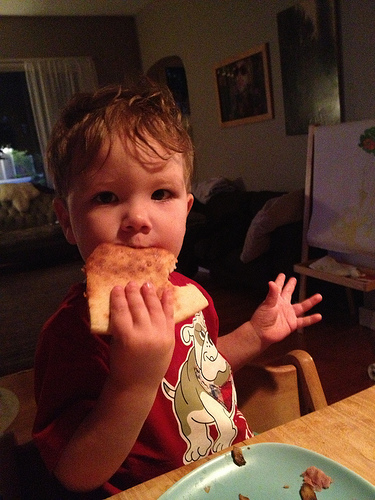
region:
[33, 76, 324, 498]
A little boy eating pizza.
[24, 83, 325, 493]
A little boy in a red shirt.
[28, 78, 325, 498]
Boy in a red shirt with a dog on it.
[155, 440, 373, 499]
A green plate.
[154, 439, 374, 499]
A plate with small pieces of meat on it.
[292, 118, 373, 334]
A wooden easel.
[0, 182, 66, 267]
A sofa.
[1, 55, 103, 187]
A window with its white curtains open.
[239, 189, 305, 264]
A white pillow on the couch.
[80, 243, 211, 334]
A partially eaten slice of pizza being held upside down.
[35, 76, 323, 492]
A boy at a dining table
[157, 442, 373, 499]
A green plate on table in front of the boy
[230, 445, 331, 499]
Food crumbs on the plate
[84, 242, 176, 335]
Toasted bread slice the boy is eating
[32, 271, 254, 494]
Red tshirt of the boy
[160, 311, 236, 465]
Print of a cartoon dog on the boy's tshirt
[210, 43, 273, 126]
A picture frame on the wall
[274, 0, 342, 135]
A canvas painting on the wall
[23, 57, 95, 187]
White curtains on the window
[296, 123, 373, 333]
A painting eisel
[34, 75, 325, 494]
a little boy eating a slice of pizza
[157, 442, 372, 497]
part of a blue plate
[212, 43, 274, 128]
a crooked picture hanging on the wall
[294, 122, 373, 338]
a wooden easel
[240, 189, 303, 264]
a pillow on the couch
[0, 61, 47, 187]
a window showing that it's night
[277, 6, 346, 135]
a picture hanging on the wall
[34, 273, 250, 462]
a bulldog on a red t-shirt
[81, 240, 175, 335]
the bottom of a slice of pizza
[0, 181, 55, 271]
a tan couch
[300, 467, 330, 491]
food on the plate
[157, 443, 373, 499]
a square plate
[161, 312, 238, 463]
a dog print on the shirt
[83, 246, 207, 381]
the boy is holding food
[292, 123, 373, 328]
an art table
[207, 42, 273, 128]
framed art on the wall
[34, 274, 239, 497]
the shirt is red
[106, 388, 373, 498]
the table is wood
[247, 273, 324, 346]
his hand is open